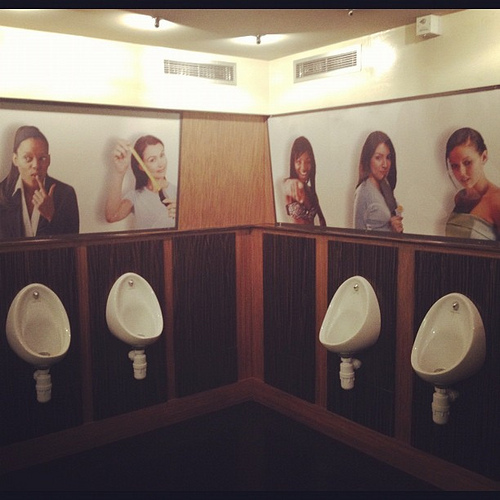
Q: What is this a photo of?
A: Urinals.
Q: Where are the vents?
A: Top of wall.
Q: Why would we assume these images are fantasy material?
A: They are displayed in a men's bathroom.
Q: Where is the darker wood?
A: In squares, surrounding each of four urinals.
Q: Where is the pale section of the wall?
A: Above the photos.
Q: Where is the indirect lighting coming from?
A: The ceiling.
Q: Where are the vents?
A: Above the photos, near the ceiling, on either side of the corner, where the walls meet.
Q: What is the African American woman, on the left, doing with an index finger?
A: Touching it to her lip.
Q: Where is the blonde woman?
A: None of the women pictured are blonde.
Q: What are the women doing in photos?
A: Smiling.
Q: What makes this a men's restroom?
A: The urinals.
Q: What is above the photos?
A: Air vents.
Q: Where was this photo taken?
A: Men's restroom.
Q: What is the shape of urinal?
A: Round.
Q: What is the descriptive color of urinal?
A: White.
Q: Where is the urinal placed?
A: On the wall.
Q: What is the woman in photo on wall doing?
A: Pointing.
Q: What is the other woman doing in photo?
A: Has finger over mouth to shh.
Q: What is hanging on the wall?
A: Urinals.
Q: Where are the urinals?
A: On the bathroom wall.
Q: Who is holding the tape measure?
A: A woman.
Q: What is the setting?
A: A bathroom.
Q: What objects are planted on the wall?
A: Urinals.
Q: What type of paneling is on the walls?
A: Wooden.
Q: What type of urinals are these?
A: Fur white.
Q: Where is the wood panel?
A: On the wall.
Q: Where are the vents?
A: Near the ceiling.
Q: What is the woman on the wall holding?
A: Tape measure.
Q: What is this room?
A: A bathroom.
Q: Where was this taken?
A: Bathroom.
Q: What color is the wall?
A: Brown.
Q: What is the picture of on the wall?
A: Women.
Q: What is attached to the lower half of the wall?
A: Urinals.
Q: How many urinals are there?
A: 4.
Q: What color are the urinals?
A: White.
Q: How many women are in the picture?
A: 5.